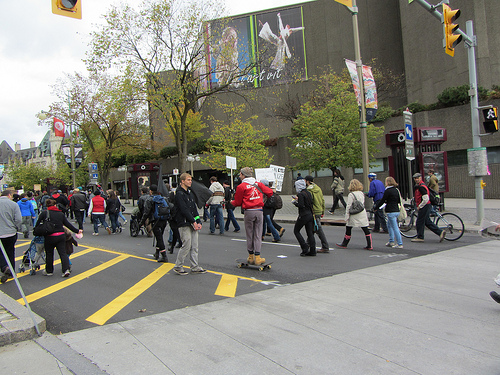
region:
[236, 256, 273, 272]
A black skateboard.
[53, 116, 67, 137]
A red flag hanging from a pole.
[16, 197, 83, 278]
A lady pushing a baby stroller.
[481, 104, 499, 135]
A sign telling people to walk.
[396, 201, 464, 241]
A bicycle that is on the road.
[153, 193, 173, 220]
A blue backpack on the back of a person.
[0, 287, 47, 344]
Part of a curb next to the road.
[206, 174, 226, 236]
A man walking in a white jacket.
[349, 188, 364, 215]
A purse on a woman's shoulder.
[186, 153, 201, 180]
A post with lights on it.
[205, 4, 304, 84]
2 large posters of things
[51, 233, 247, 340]
sidewalk with yellow bars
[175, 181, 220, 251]
man holding green object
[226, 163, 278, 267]
man on a skateboard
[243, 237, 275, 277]
man wearing dog boots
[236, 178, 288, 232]
man with a red jacket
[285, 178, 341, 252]
person wearing black and grey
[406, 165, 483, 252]
person with a bike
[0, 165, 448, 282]
People on the street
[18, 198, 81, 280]
Woman pushing a stroller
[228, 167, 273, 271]
Man on a skateboard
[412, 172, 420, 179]
The hat is gray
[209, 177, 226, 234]
A man is walking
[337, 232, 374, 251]
Black and pink boots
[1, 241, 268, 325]
Yellow line on road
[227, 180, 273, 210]
The jacket is red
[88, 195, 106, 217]
A red and white jacket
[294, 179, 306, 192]
The hood is gray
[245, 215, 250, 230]
man wearing grey pants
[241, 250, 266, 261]
man wearing tan boots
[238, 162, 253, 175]
man wearing grey hat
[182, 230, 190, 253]
man wearing grey jeans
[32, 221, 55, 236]
black purse on womans shirt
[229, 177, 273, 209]
red jacket skateboarder is wearing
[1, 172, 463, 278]
crowd of people walking down the street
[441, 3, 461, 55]
yellow traffic light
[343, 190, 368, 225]
white coat woman is wearing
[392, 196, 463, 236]
black bicycle on the street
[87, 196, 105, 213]
red and white top person is wearing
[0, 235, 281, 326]
yellow strips in the road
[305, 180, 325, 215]
man wearing a green jacket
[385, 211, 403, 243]
blue jeans woman is wearing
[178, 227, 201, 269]
khaki colored pants man is wearing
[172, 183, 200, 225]
jacket worn by human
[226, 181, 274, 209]
jacket worn by human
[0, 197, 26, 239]
jacket worn by human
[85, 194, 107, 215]
jacket worn by human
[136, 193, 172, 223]
jacket worn by human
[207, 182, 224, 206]
jacket worn by human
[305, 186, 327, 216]
jacket worn by human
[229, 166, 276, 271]
a person riding a skateboard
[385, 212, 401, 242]
a pair of blue jeans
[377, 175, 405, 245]
a pedestrian on street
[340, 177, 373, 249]
a pedestrian on street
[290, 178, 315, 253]
a pedestrian on street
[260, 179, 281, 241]
a pedestrian on street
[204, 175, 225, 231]
a pedestrian on street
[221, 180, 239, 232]
a pedestrian on street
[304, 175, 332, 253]
A person walking on a street.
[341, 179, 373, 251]
A person walking on a street.